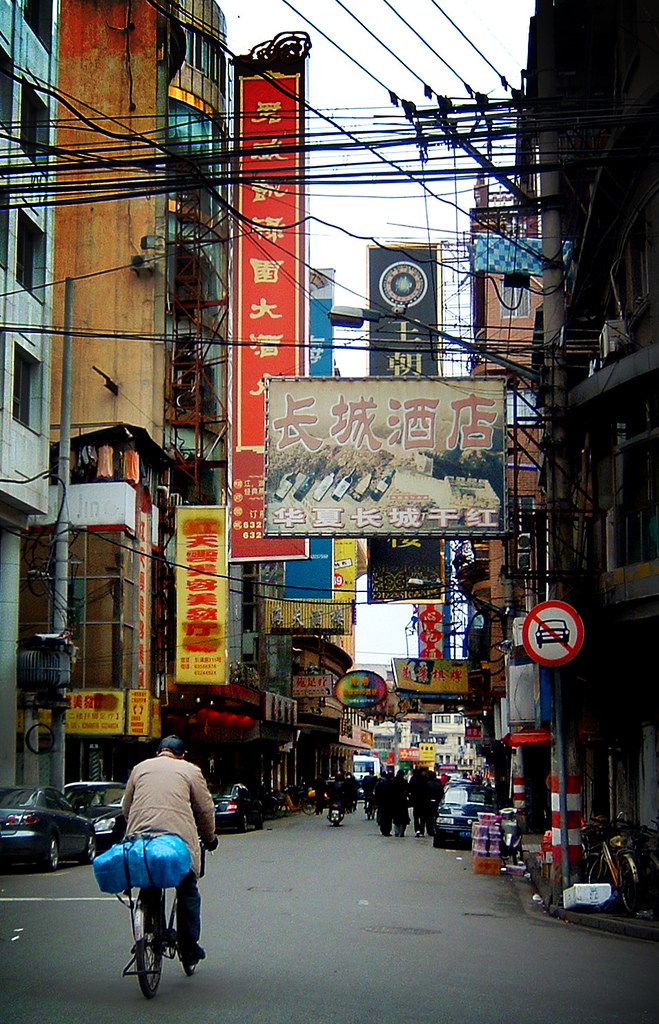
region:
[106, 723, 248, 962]
man riding bicycle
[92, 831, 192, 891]
blue bag on the bicycle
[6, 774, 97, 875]
gray car on the street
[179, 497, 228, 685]
yellow vertical sign with red lettering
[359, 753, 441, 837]
men walking on the street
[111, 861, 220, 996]
bicycle man is riding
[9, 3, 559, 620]
black wires above the street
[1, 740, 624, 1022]
street the bicycle is on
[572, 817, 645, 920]
bicycle on the sidewalk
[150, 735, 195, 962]
A man riding a bicycle on the street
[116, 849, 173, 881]
A blue package on a bicycle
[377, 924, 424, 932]
A manhole in the middle of the street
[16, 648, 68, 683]
An electricity transformer on a pole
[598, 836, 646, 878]
Bicycles parked on the side walk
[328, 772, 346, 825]
A person riding a bicycle on the street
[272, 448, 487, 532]
A sign board hanging across the street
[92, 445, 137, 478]
Clothes hanging on a balcony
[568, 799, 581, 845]
A pillar painted red and white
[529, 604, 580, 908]
a street sign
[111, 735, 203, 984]
a person riding a bicycle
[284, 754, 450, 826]
people walking on the street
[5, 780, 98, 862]
a car parked on the street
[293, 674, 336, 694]
a sign on the building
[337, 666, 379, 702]
a colorful sign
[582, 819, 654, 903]
bicycles on the sidewalk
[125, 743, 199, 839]
a person in a tan jacket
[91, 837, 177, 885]
a blue bag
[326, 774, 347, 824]
a person on a motorcycle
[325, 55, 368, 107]
a view of sky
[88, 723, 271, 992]
a man in the road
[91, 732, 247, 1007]
a man in the cycle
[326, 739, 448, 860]
a group of people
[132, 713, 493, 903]
a view of street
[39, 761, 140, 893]
a view of cars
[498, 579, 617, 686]
a view of board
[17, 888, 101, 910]
White line on the street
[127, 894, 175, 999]
Tire on a bike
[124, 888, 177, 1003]
Black tire on a bike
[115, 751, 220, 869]
Coat on a man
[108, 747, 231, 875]
Brown coat on a man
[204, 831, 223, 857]
Glove on a hand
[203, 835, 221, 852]
Black glove on a hand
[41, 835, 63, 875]
Tire of a car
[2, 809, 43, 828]
Taillight of a car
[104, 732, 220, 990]
man in tan jacket riding a bike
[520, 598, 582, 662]
a sign indicating no cars allowed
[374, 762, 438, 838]
group of people walking down the road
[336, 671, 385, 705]
rainbow colored store sign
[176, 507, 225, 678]
long red and yellow store sign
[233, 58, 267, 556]
very large red sign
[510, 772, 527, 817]
red and white stripes painted on pillar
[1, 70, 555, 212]
electrical wires going in all directions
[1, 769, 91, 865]
blue sedan parked on the road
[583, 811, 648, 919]
bikes parked on the street corner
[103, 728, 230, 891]
man riding bicycle